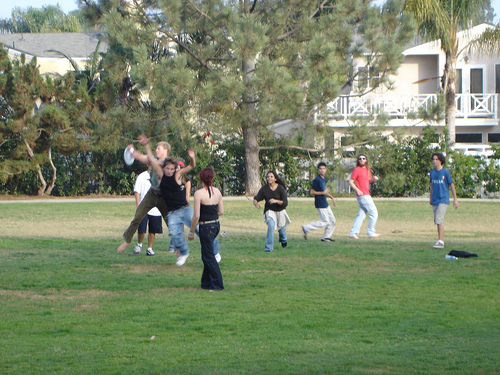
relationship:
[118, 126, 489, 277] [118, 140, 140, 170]
group playing frisbee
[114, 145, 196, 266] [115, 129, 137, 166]
boy jumping for frisbee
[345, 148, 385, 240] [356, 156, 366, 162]
boy wearing sunglasses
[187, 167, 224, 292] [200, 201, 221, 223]
girl wearing tube top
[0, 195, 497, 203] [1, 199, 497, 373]
walkway around park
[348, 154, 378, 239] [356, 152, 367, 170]
boy has hair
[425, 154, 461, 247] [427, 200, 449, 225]
boy wearing shorts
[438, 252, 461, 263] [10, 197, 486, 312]
bottle on ground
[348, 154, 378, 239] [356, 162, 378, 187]
boy wearing red shirt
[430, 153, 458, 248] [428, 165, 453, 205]
boy wearing blue shirt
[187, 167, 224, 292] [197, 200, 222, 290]
girl wearing black outfit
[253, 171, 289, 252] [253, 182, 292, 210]
kid wearing shirt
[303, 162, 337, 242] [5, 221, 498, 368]
guy running grass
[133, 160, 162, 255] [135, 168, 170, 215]
man wearing white shirt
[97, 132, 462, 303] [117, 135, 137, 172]
people playing frisbee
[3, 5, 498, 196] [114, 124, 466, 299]
trees behind people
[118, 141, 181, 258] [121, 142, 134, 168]
boy catching frisbee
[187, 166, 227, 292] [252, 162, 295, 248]
girl chased by kid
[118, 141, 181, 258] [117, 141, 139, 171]
boy playing frisbee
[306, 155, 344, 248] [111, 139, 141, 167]
guy running for frisbee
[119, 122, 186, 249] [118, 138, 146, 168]
boy caught frisbee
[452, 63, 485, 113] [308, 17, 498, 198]
door of home